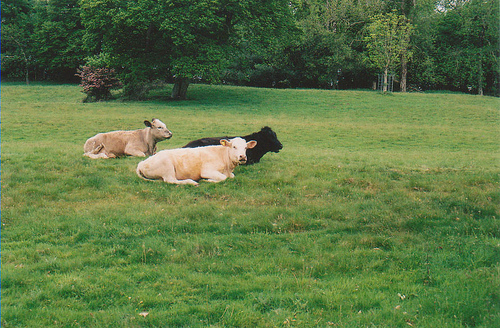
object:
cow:
[81, 117, 174, 161]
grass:
[1, 82, 500, 327]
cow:
[133, 135, 259, 188]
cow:
[182, 125, 286, 167]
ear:
[143, 119, 153, 127]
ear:
[218, 139, 229, 148]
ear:
[246, 139, 258, 149]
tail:
[134, 163, 165, 184]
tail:
[81, 147, 111, 160]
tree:
[357, 7, 424, 96]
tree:
[398, 0, 415, 94]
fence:
[375, 70, 394, 95]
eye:
[157, 126, 164, 130]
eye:
[233, 145, 238, 150]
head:
[143, 117, 174, 140]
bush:
[71, 63, 122, 104]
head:
[257, 125, 285, 154]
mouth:
[275, 145, 284, 154]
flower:
[110, 68, 116, 72]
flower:
[88, 74, 92, 77]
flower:
[113, 80, 116, 82]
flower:
[88, 85, 95, 89]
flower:
[95, 67, 101, 72]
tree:
[76, 0, 171, 102]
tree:
[152, 0, 253, 100]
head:
[217, 136, 257, 167]